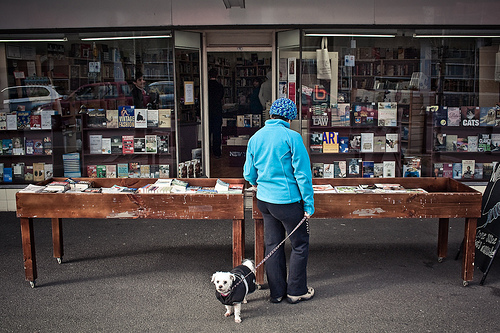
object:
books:
[311, 104, 330, 127]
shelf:
[308, 103, 402, 178]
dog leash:
[233, 213, 310, 288]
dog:
[210, 259, 255, 323]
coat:
[215, 265, 256, 306]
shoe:
[286, 286, 315, 304]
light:
[81, 35, 171, 41]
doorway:
[176, 29, 303, 178]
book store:
[0, 29, 499, 188]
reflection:
[31, 82, 149, 117]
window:
[0, 34, 176, 186]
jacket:
[243, 119, 316, 215]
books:
[214, 179, 228, 190]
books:
[228, 184, 243, 191]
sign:
[184, 81, 195, 105]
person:
[242, 97, 316, 304]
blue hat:
[271, 98, 297, 119]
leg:
[20, 219, 37, 280]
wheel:
[29, 281, 35, 288]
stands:
[16, 178, 245, 289]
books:
[19, 184, 46, 194]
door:
[205, 48, 273, 178]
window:
[300, 31, 500, 178]